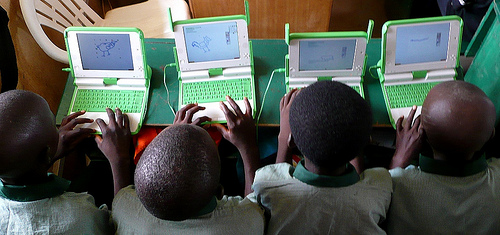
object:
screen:
[183, 20, 240, 64]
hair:
[1, 91, 44, 161]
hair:
[133, 126, 216, 221]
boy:
[0, 89, 133, 234]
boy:
[113, 95, 268, 233]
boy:
[251, 76, 395, 233]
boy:
[386, 80, 499, 234]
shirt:
[1, 174, 114, 233]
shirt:
[111, 185, 269, 233]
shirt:
[248, 157, 396, 234]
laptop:
[58, 24, 155, 136]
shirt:
[388, 153, 499, 233]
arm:
[112, 164, 129, 194]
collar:
[292, 160, 360, 188]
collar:
[413, 153, 488, 175]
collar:
[0, 172, 73, 202]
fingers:
[394, 116, 404, 135]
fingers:
[189, 115, 209, 125]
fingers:
[94, 134, 101, 144]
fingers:
[70, 128, 97, 135]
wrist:
[233, 141, 258, 153]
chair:
[16, 0, 192, 63]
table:
[53, 36, 478, 129]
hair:
[289, 82, 369, 159]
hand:
[393, 106, 425, 154]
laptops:
[273, 19, 375, 103]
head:
[418, 80, 496, 168]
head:
[290, 80, 375, 168]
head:
[134, 123, 225, 222]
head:
[0, 90, 60, 181]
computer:
[53, 26, 155, 138]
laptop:
[166, 13, 254, 125]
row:
[6, 82, 499, 233]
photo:
[0, 1, 495, 233]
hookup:
[155, 59, 189, 120]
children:
[2, 82, 498, 229]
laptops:
[367, 15, 460, 131]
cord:
[162, 64, 176, 123]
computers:
[173, 15, 263, 125]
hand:
[211, 95, 259, 146]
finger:
[211, 123, 228, 135]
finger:
[218, 101, 236, 122]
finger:
[226, 96, 244, 116]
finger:
[244, 97, 252, 116]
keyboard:
[382, 81, 445, 109]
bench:
[0, 171, 499, 234]